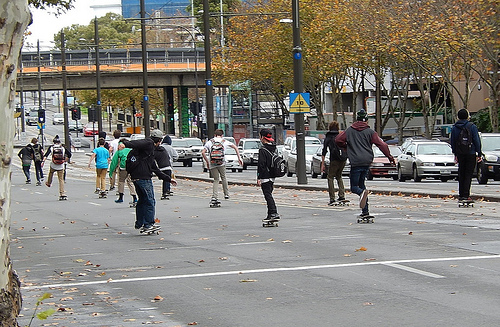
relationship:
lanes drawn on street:
[16, 250, 500, 293] [10, 113, 499, 325]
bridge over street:
[34, 60, 194, 73] [53, 195, 103, 276]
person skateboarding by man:
[350, 112, 387, 211] [255, 128, 291, 223]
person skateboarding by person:
[350, 112, 387, 211] [138, 120, 171, 221]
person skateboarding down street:
[350, 112, 387, 211] [18, 131, 434, 299]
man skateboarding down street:
[255, 128, 291, 223] [18, 131, 434, 299]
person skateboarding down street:
[138, 120, 171, 221] [18, 131, 434, 299]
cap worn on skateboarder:
[256, 127, 275, 143] [254, 126, 286, 228]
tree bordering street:
[300, 0, 372, 131] [221, 250, 440, 296]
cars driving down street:
[235, 137, 266, 171] [10, 113, 499, 325]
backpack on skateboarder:
[261, 142, 289, 182] [251, 119, 294, 230]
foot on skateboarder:
[349, 174, 383, 210] [328, 97, 403, 236]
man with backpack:
[255, 128, 291, 223] [258, 142, 292, 177]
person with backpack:
[190, 120, 237, 209] [205, 136, 225, 166]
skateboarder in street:
[448, 106, 483, 204] [10, 113, 499, 325]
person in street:
[333, 108, 397, 220] [10, 113, 499, 325]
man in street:
[255, 128, 291, 223] [10, 113, 499, 325]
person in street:
[199, 128, 245, 204] [10, 113, 499, 325]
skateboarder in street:
[120, 127, 177, 234] [10, 113, 499, 325]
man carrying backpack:
[256, 127, 285, 231] [260, 144, 289, 178]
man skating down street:
[255, 128, 291, 223] [8, 141, 497, 322]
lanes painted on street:
[16, 250, 500, 293] [8, 141, 497, 322]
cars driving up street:
[392, 137, 457, 187] [10, 113, 499, 325]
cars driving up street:
[374, 146, 400, 175] [10, 113, 499, 325]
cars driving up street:
[285, 148, 317, 176] [10, 113, 499, 325]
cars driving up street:
[241, 138, 263, 161] [10, 113, 499, 325]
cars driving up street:
[171, 136, 193, 170] [10, 113, 499, 325]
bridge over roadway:
[98, 21, 220, 67] [12, 107, 252, 194]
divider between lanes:
[388, 170, 455, 213] [1, 103, 497, 317]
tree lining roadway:
[435, 0, 498, 136] [1, 102, 497, 324]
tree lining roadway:
[302, 0, 372, 132] [1, 102, 497, 324]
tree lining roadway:
[211, 0, 298, 130] [1, 102, 497, 324]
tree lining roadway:
[383, 0, 448, 133] [1, 102, 497, 324]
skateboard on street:
[261, 215, 278, 228] [6, 162, 498, 324]